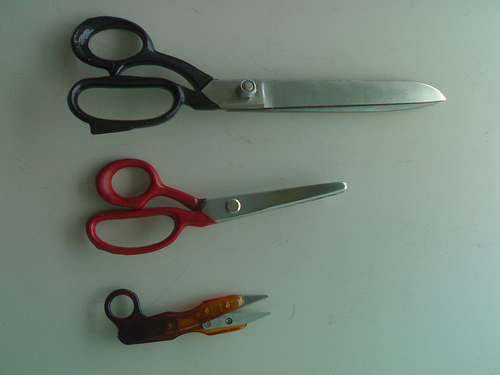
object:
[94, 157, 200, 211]
handle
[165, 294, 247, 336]
brown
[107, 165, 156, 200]
round hole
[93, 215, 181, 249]
oval hole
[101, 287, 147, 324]
handle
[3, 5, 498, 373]
table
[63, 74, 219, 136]
handle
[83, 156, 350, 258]
scissors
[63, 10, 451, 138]
blade scissors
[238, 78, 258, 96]
bolts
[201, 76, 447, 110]
blades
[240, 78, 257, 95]
screw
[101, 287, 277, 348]
scissors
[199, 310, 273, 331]
blade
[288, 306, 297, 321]
hair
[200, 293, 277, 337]
raised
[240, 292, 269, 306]
blade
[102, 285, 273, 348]
smallest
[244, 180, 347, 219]
silver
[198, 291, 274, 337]
ajar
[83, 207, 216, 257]
handled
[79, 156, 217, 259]
red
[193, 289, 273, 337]
upper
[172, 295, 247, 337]
color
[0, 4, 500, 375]
surface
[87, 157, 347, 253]
medium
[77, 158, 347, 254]
all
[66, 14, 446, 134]
large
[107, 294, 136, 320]
round